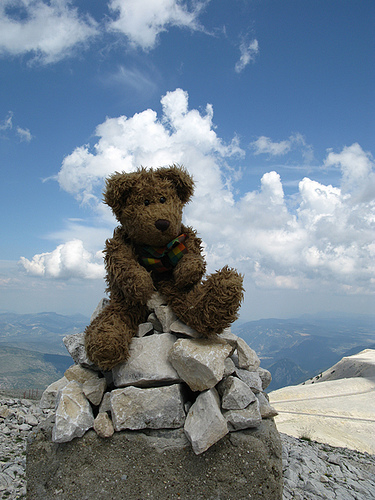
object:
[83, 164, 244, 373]
teddy bear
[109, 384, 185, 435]
rocks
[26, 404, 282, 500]
base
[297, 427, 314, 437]
grass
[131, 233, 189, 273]
ribbon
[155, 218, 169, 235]
nose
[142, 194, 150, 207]
eye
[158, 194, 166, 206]
eye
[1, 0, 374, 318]
sky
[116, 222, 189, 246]
neck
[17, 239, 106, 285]
clouds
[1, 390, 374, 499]
ground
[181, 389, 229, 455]
rocks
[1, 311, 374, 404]
mountains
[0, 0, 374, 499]
background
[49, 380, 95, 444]
rocks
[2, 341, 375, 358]
road